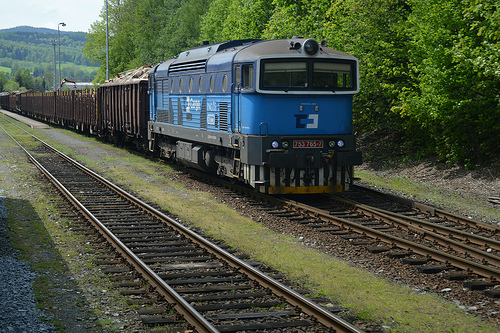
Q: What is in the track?
A: Train.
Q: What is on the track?
A: Train.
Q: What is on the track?
A: Train.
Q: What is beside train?
A: Bushes.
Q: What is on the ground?
A: Track.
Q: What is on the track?
A: Train.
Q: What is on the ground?
A: Track.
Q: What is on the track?
A: Train.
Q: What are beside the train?
A: Leaves.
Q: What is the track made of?
A: Metal.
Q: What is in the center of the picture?
A: A train.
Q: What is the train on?
A: The tracks.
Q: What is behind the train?
A: Trees,.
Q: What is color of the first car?
A: Blue.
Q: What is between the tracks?
A: Gravel.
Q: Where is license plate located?
A: On the front of the train.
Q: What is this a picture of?
A: A train.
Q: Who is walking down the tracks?
A: No one.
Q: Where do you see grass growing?
A: Next to the tracks.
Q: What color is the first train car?
A: Blue.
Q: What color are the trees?
A: Green.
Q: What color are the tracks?
A: Rusty brown.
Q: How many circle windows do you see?
A: 6.